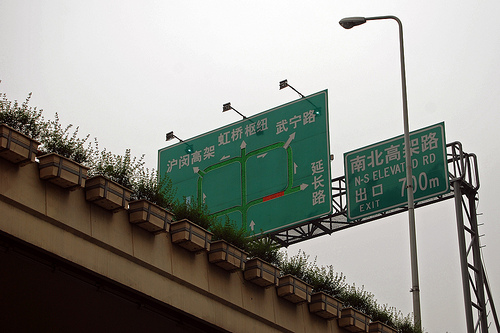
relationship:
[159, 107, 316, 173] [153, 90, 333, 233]
writing on sign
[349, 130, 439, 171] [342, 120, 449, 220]
writing on sign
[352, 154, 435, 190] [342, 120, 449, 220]
writing on sign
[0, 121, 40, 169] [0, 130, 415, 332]
planter on roadway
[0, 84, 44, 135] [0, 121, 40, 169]
plant in planter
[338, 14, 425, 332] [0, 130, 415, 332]
street lamp next to roadway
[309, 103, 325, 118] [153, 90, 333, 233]
light on sign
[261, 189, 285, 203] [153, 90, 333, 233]
mark on sign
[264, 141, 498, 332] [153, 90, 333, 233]
sign support behind sign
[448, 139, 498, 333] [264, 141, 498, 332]
ladder on sign support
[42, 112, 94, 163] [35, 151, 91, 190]
plant in planter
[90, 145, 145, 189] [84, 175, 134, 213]
plant in planter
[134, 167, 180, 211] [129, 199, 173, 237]
plant in planter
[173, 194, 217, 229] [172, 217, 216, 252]
plant in planter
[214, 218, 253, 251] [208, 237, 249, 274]
plant in planter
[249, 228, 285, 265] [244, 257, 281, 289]
plant in planter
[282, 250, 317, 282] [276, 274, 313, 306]
plant in planter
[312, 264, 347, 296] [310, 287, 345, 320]
plant in planter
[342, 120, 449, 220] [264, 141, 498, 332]
sign on sign support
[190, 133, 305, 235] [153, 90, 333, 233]
map on sign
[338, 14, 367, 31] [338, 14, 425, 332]
light on street lamp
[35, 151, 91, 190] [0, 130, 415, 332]
planter on roadway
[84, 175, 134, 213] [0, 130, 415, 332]
planter on roadway